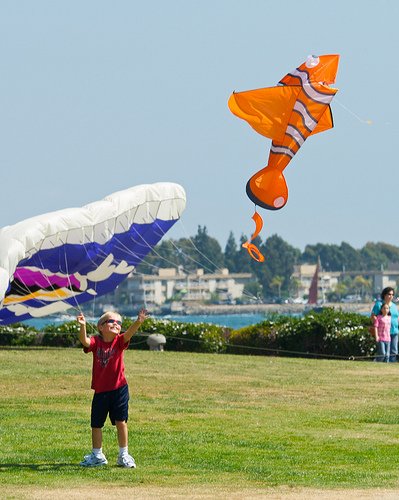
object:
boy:
[76, 307, 151, 468]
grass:
[0, 345, 398, 500]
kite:
[227, 53, 341, 262]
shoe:
[78, 452, 109, 468]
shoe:
[116, 452, 137, 469]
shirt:
[83, 332, 130, 394]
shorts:
[90, 384, 129, 428]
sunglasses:
[100, 318, 123, 326]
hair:
[97, 311, 122, 336]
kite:
[0, 181, 187, 326]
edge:
[0, 181, 187, 310]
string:
[57, 231, 101, 336]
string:
[85, 229, 261, 302]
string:
[119, 213, 259, 301]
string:
[142, 210, 259, 300]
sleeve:
[118, 332, 131, 350]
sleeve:
[83, 336, 96, 354]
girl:
[372, 302, 392, 362]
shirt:
[373, 314, 392, 342]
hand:
[76, 312, 86, 326]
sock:
[118, 445, 128, 456]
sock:
[92, 447, 102, 457]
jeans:
[377, 341, 391, 363]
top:
[223, 231, 239, 275]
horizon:
[31, 223, 398, 319]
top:
[341, 241, 363, 270]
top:
[236, 232, 251, 273]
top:
[135, 239, 180, 273]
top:
[168, 236, 201, 268]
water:
[20, 311, 371, 330]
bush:
[1, 322, 39, 347]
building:
[85, 264, 251, 310]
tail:
[241, 166, 289, 263]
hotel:
[290, 263, 398, 304]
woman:
[370, 287, 398, 362]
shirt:
[371, 299, 398, 335]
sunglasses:
[387, 292, 394, 297]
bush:
[40, 319, 96, 348]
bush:
[122, 314, 233, 354]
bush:
[226, 305, 377, 361]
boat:
[302, 255, 327, 317]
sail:
[308, 254, 326, 307]